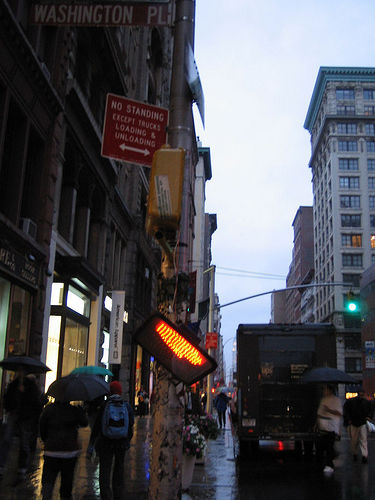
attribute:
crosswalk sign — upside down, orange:
[139, 319, 219, 388]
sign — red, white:
[100, 90, 167, 169]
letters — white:
[113, 101, 162, 147]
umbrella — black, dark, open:
[49, 374, 109, 402]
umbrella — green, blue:
[71, 364, 118, 378]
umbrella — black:
[302, 362, 357, 394]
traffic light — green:
[345, 289, 360, 318]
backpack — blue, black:
[100, 401, 132, 441]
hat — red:
[108, 378, 124, 395]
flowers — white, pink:
[182, 424, 206, 456]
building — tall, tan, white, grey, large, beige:
[303, 61, 374, 438]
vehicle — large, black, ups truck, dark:
[235, 322, 339, 471]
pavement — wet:
[13, 450, 133, 499]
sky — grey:
[208, 8, 372, 322]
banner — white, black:
[110, 287, 127, 366]